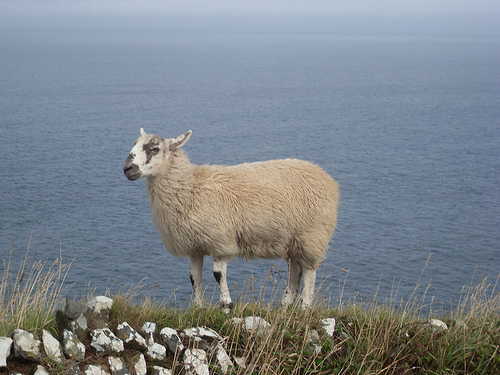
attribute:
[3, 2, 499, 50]
sky — hazy, blue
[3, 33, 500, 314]
water — choppy, grey-blue, beautiful, blue, calm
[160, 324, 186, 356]
rock — brown, white, dark grey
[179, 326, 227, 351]
rock — brown, white, dark grey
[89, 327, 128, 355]
rock — brown, white, dark grey, from a wall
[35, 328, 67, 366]
rock — brown, white, dark grey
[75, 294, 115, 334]
rock — brown, white, dark grey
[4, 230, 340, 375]
grass — growing, green, yellow, brown, white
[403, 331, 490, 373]
weeds — growing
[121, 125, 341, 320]
goat — hairy, white, standing, posing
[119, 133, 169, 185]
face — black, white, brown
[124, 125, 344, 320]
sheep — standing, looking left, tan, white, alone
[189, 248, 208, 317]
front leg — white, muddy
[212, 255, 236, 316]
front leg — white, muddy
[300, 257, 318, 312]
hind leg — white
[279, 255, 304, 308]
hind leg — white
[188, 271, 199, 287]
spot — black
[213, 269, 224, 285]
spot — black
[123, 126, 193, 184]
head — black, white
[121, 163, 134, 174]
nose — black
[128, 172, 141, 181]
mouth — black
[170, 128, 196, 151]
ear — facing back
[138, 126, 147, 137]
ear — facing back